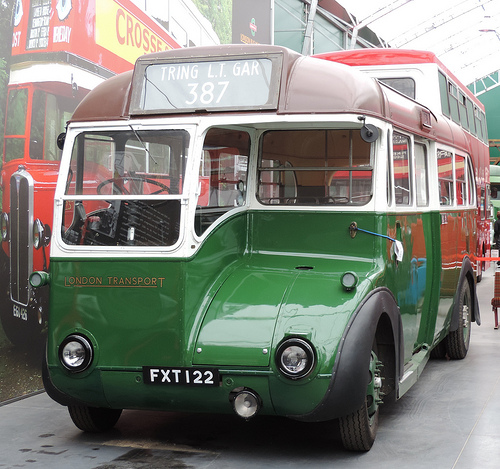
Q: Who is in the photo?
A: Nobody.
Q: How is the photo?
A: Clear.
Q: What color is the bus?
A: Green.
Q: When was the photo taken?
A: Daytime.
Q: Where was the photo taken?
A: At a bus stop.